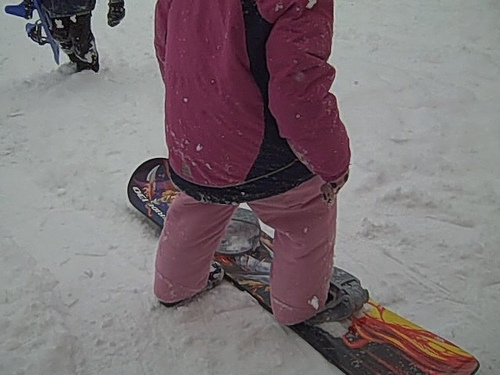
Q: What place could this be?
A: It is a field.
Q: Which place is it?
A: It is a field.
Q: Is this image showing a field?
A: Yes, it is showing a field.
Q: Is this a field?
A: Yes, it is a field.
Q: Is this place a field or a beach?
A: It is a field.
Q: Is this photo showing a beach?
A: No, the picture is showing a field.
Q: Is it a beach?
A: No, it is a field.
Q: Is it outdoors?
A: Yes, it is outdoors.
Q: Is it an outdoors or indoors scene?
A: It is outdoors.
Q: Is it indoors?
A: No, it is outdoors.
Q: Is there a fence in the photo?
A: No, there are no fences.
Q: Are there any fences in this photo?
A: No, there are no fences.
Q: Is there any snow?
A: Yes, there is snow.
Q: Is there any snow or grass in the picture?
A: Yes, there is snow.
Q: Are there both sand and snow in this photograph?
A: No, there is snow but no sand.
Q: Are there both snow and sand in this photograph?
A: No, there is snow but no sand.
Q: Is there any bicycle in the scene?
A: No, there are no bicycles.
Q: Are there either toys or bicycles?
A: No, there are no bicycles or toys.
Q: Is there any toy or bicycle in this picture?
A: No, there are no bicycles or toys.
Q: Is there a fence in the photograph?
A: No, there are no fences.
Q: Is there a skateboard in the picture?
A: Yes, there is a skateboard.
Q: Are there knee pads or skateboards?
A: Yes, there is a skateboard.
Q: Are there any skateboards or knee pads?
A: Yes, there is a skateboard.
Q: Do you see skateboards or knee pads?
A: Yes, there is a skateboard.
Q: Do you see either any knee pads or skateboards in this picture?
A: Yes, there is a skateboard.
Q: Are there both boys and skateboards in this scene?
A: Yes, there are both a skateboard and a boy.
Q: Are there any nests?
A: No, there are no nests.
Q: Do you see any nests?
A: No, there are no nests.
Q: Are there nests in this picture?
A: No, there are no nests.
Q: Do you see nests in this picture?
A: No, there are no nests.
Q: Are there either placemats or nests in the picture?
A: No, there are no nests or placemats.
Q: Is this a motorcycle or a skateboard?
A: This is a skateboard.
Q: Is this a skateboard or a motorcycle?
A: This is a skateboard.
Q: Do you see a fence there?
A: No, there are no fences.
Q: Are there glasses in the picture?
A: No, there are no glasses.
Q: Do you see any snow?
A: Yes, there is snow.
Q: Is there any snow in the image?
A: Yes, there is snow.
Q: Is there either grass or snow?
A: Yes, there is snow.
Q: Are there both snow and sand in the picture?
A: No, there is snow but no sand.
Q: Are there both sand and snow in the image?
A: No, there is snow but no sand.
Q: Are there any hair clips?
A: No, there are no hair clips.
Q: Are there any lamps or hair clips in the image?
A: No, there are no hair clips or lamps.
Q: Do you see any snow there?
A: Yes, there is snow.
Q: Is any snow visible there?
A: Yes, there is snow.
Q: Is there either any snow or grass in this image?
A: Yes, there is snow.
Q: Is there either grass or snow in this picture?
A: Yes, there is snow.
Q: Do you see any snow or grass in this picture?
A: Yes, there is snow.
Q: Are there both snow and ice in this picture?
A: No, there is snow but no ice.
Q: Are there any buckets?
A: No, there are no buckets.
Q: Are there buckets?
A: No, there are no buckets.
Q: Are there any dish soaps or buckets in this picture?
A: No, there are no buckets or dish soaps.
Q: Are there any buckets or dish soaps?
A: No, there are no buckets or dish soaps.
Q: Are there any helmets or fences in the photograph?
A: No, there are no fences or helmets.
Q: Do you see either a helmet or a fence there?
A: No, there are no fences or helmets.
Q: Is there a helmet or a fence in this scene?
A: No, there are no fences or helmets.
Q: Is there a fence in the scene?
A: No, there are no fences.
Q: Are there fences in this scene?
A: No, there are no fences.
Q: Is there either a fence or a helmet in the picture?
A: No, there are no fences or helmets.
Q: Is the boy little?
A: Yes, the boy is little.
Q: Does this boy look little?
A: Yes, the boy is little.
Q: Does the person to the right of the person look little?
A: Yes, the boy is little.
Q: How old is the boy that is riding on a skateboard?
A: The boy is little.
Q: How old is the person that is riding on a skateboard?
A: The boy is little.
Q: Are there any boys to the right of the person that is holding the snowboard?
A: Yes, there is a boy to the right of the person.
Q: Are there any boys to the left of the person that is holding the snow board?
A: No, the boy is to the right of the person.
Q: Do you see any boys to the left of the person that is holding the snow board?
A: No, the boy is to the right of the person.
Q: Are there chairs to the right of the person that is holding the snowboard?
A: No, there is a boy to the right of the person.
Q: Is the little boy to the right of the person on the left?
A: Yes, the boy is to the right of the person.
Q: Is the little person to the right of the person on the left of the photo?
A: Yes, the boy is to the right of the person.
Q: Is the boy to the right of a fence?
A: No, the boy is to the right of the person.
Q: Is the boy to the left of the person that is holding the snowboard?
A: No, the boy is to the right of the person.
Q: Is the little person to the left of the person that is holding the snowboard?
A: No, the boy is to the right of the person.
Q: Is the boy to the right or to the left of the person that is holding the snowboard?
A: The boy is to the right of the person.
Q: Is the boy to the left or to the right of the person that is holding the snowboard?
A: The boy is to the right of the person.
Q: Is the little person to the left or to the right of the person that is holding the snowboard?
A: The boy is to the right of the person.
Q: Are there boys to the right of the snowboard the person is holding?
A: Yes, there is a boy to the right of the snowboard.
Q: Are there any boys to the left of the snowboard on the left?
A: No, the boy is to the right of the snowboard.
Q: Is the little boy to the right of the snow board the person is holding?
A: Yes, the boy is to the right of the snowboard.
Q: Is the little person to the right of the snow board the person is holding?
A: Yes, the boy is to the right of the snowboard.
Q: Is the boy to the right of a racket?
A: No, the boy is to the right of the snowboard.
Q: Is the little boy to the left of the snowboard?
A: No, the boy is to the right of the snowboard.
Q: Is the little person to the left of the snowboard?
A: No, the boy is to the right of the snowboard.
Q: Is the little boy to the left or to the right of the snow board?
A: The boy is to the right of the snow board.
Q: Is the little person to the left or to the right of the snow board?
A: The boy is to the right of the snow board.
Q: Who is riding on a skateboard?
A: The boy is riding on a skateboard.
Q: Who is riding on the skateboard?
A: The boy is riding on a skateboard.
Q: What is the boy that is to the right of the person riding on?
A: The boy is riding on a skateboard.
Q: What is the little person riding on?
A: The boy is riding on a skateboard.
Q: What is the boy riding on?
A: The boy is riding on a skateboard.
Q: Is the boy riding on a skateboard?
A: Yes, the boy is riding on a skateboard.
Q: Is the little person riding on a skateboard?
A: Yes, the boy is riding on a skateboard.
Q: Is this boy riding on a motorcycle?
A: No, the boy is riding on a skateboard.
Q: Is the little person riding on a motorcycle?
A: No, the boy is riding on a skateboard.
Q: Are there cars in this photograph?
A: No, there are no cars.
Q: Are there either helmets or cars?
A: No, there are no cars or helmets.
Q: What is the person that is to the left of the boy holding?
A: The person is holding the snowboard.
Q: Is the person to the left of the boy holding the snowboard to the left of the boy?
A: Yes, the person is holding the snowboard.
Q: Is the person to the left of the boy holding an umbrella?
A: No, the person is holding the snowboard.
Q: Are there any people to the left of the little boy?
A: Yes, there is a person to the left of the boy.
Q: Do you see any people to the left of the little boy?
A: Yes, there is a person to the left of the boy.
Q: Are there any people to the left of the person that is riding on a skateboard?
A: Yes, there is a person to the left of the boy.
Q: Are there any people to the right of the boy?
A: No, the person is to the left of the boy.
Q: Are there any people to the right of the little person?
A: No, the person is to the left of the boy.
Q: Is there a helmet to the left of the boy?
A: No, there is a person to the left of the boy.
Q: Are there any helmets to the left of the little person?
A: No, there is a person to the left of the boy.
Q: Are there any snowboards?
A: Yes, there is a snowboard.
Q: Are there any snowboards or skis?
A: Yes, there is a snowboard.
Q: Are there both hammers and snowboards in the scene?
A: No, there is a snowboard but no hammers.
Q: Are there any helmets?
A: No, there are no helmets.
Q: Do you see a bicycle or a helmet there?
A: No, there are no helmets or bicycles.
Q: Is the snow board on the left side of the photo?
A: Yes, the snow board is on the left of the image.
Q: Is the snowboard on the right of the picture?
A: No, the snowboard is on the left of the image.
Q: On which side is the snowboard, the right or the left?
A: The snowboard is on the left of the image.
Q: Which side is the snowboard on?
A: The snowboard is on the left of the image.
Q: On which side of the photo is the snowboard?
A: The snowboard is on the left of the image.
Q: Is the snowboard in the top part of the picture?
A: Yes, the snowboard is in the top of the image.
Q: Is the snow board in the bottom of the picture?
A: No, the snow board is in the top of the image.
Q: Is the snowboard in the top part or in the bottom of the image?
A: The snowboard is in the top of the image.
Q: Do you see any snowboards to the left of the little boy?
A: Yes, there is a snowboard to the left of the boy.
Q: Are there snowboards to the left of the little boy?
A: Yes, there is a snowboard to the left of the boy.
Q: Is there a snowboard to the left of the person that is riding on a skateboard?
A: Yes, there is a snowboard to the left of the boy.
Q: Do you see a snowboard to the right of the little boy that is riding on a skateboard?
A: No, the snowboard is to the left of the boy.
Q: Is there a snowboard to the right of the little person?
A: No, the snowboard is to the left of the boy.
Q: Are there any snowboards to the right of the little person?
A: No, the snowboard is to the left of the boy.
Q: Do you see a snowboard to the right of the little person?
A: No, the snowboard is to the left of the boy.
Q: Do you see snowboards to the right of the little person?
A: No, the snowboard is to the left of the boy.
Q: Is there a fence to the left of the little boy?
A: No, there is a snowboard to the left of the boy.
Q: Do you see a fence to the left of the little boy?
A: No, there is a snowboard to the left of the boy.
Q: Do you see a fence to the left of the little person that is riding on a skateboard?
A: No, there is a snowboard to the left of the boy.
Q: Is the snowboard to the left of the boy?
A: Yes, the snowboard is to the left of the boy.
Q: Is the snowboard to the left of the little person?
A: Yes, the snowboard is to the left of the boy.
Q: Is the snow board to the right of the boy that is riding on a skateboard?
A: No, the snow board is to the left of the boy.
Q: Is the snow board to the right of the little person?
A: No, the snow board is to the left of the boy.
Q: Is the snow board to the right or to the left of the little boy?
A: The snow board is to the left of the boy.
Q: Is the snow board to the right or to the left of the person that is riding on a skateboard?
A: The snow board is to the left of the boy.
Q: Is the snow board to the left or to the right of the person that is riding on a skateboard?
A: The snow board is to the left of the boy.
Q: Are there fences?
A: No, there are no fences.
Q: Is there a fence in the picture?
A: No, there are no fences.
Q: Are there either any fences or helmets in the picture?
A: No, there are no fences or helmets.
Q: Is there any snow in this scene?
A: Yes, there is snow.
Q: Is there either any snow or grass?
A: Yes, there is snow.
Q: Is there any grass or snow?
A: Yes, there is snow.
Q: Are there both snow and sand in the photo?
A: No, there is snow but no sand.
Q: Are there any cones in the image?
A: No, there are no cones.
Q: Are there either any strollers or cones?
A: No, there are no cones or strollers.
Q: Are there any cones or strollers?
A: No, there are no cones or strollers.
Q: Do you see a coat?
A: Yes, there is a coat.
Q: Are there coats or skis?
A: Yes, there is a coat.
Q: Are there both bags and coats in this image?
A: No, there is a coat but no bags.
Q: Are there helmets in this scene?
A: No, there are no helmets.